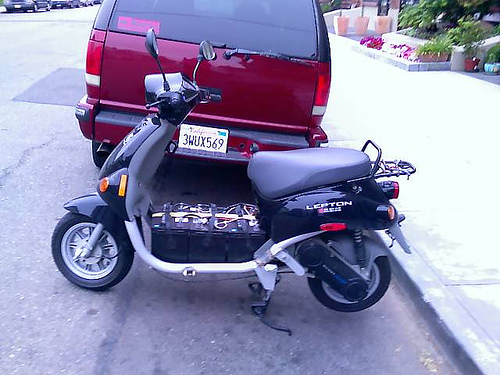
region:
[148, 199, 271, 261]
three batteries on a scooter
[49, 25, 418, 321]
a scooter behind a vehicle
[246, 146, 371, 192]
a gray padded seat on a scooter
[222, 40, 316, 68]
a windshield wiper on a rear window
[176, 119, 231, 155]
a license plate on a vehicle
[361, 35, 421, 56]
a bed of flowers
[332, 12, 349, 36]
an orange clay pot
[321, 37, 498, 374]
a concrete sidewalk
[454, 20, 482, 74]
a potted plant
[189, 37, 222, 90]
a mirror on the side of a scooter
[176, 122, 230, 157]
White license plate on back of automobile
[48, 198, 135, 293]
Front tire of moped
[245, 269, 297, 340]
Kickstand holding moped up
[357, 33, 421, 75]
Several flowers lining the sidewalk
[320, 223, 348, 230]
Red reflector on moped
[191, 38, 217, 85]
Right side view mirror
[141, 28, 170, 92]
Left side view mirror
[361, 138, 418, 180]
Luggage rack on moped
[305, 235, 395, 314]
Rear tire of moped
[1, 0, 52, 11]
Blue car parked on side of road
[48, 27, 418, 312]
Scooter parked behind red car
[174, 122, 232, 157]
California license plate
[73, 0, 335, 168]
Red car parked at curb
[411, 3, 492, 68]
Plants in pots alongside sidewalk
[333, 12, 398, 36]
Three terra-cotta planters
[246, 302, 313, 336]
Kickstand from scooter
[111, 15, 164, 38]
Sticker on left back car window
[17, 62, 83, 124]
Patched spot in the road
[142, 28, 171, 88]
Mirror attached to the scooter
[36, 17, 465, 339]
Motorcycle on the road.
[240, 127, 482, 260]
Seat on the motorcycle.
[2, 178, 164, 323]
Wheel on the motorcycle.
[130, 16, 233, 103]
Mirrors on the motorcycle.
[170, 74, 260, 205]
License on the suv.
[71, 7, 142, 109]
Lights on the SUV.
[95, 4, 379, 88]
Windows on the SUV.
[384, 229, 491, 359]
Curb by the motorcycle.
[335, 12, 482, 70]
Flowers in the background.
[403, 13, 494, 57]
Plants by the flowers.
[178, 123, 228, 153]
A license plate on a car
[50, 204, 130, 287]
Wheel on a moped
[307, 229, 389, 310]
Rear wheel on a moped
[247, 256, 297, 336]
Kickstand on a moped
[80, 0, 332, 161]
An SUV parked in front of a moped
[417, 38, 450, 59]
A plant growing on a sidewalk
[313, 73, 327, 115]
Rear light on an SUV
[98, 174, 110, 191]
Light on a moped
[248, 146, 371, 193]
The seat on a moped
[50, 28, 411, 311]
A black moped parked